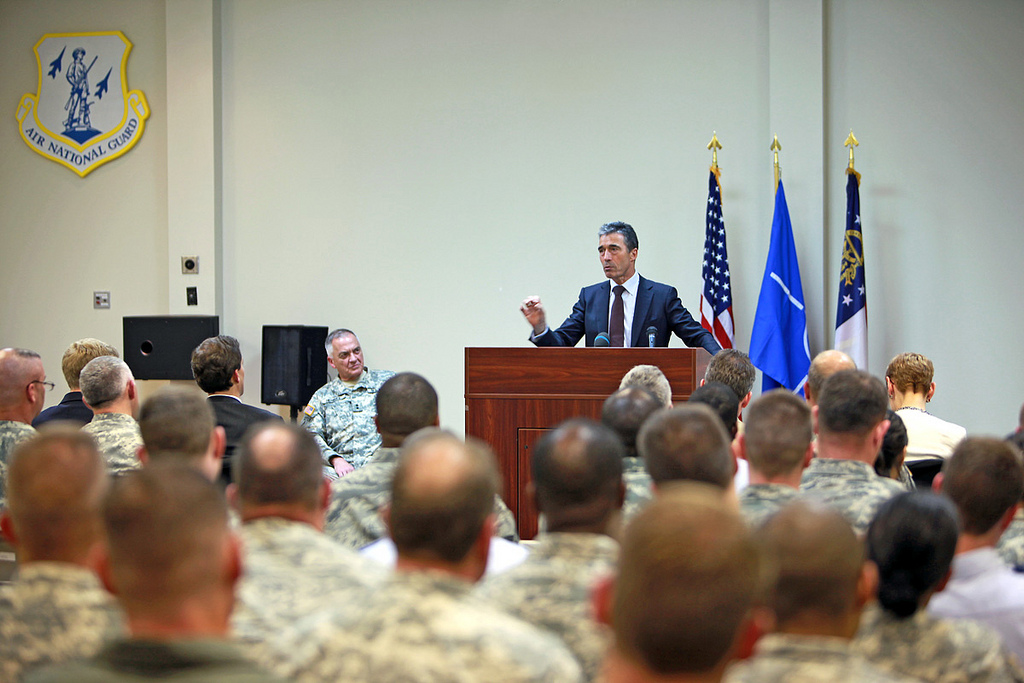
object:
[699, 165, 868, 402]
flags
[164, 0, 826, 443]
wall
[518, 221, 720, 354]
man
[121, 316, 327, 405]
speakers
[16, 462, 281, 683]
people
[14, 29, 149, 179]
logo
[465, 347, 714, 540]
podium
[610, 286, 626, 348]
tie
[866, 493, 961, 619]
hair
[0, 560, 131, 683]
uniforms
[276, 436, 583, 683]
man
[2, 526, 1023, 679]
back